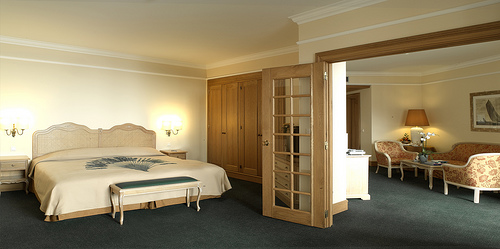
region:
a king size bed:
[14, 69, 265, 229]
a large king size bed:
[29, 78, 247, 247]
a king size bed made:
[11, 76, 236, 244]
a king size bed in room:
[22, 86, 201, 243]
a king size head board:
[22, 88, 226, 244]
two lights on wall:
[10, 63, 219, 160]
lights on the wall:
[4, 69, 199, 177]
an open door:
[239, 26, 375, 241]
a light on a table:
[373, 76, 490, 211]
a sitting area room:
[319, 73, 493, 215]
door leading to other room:
[250, 57, 352, 232]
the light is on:
[159, 105, 188, 145]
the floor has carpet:
[376, 208, 421, 244]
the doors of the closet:
[213, 80, 249, 171]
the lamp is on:
[400, 100, 427, 156]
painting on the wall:
[466, 84, 498, 139]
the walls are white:
[114, 74, 149, 114]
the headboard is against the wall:
[26, 115, 169, 153]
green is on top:
[98, 178, 240, 204]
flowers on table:
[417, 128, 437, 174]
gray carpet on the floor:
[150, 220, 267, 232]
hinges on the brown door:
[314, 202, 340, 228]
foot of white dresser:
[347, 188, 386, 214]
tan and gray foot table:
[99, 174, 213, 227]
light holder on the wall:
[155, 103, 195, 145]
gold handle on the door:
[253, 136, 272, 149]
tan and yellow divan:
[368, 133, 432, 187]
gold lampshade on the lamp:
[396, 95, 427, 129]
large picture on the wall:
[459, 87, 493, 141]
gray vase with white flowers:
[413, 121, 438, 166]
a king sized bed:
[30, 121, 231, 220]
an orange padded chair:
[371, 138, 418, 179]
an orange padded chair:
[441, 150, 497, 202]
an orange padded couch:
[432, 140, 498, 167]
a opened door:
[258, 63, 330, 228]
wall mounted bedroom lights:
[156, 108, 182, 138]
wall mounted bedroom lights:
[0, 108, 32, 140]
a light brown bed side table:
[0, 153, 30, 196]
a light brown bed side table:
[159, 147, 186, 161]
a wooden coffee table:
[398, 150, 448, 187]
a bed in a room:
[25, 73, 242, 247]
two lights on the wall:
[2, 59, 239, 212]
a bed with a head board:
[3, 62, 233, 229]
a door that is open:
[250, 30, 401, 247]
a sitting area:
[369, 97, 495, 217]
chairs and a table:
[353, 101, 496, 225]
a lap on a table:
[378, 86, 442, 165]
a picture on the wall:
[457, 78, 499, 133]